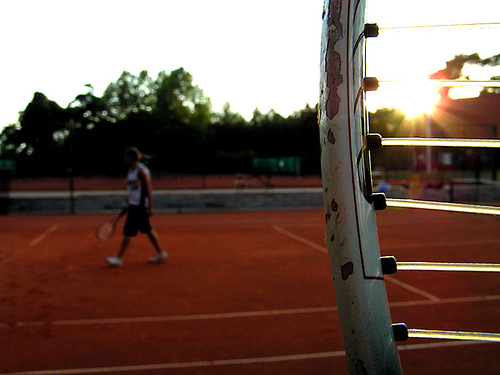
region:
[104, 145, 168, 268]
tennis player on court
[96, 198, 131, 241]
tennis racket in player's hand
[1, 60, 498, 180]
trees in back of court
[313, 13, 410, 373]
pole holding cables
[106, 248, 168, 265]
sneakers on player's feet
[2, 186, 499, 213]
wall around tennis court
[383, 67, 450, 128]
sun in sky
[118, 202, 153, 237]
black shorts on player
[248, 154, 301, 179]
green container in background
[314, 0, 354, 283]
rust on pole near tennis court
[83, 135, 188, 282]
a tennis player on tennis court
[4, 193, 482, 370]
a red tennis court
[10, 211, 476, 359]
white lines on tennis court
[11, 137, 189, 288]
tennis player walks to the left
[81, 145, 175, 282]
tennis player holds a racket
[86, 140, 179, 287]
tennis player holds racket in right hand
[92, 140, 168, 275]
tennis player wears a top tank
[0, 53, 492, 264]
trees behind tennis court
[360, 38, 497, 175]
sun rays behind trees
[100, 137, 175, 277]
man wears black pants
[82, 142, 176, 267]
a person playing tennis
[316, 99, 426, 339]
a silver metal pole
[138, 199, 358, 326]
a red tennis court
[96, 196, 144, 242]
a tennis racket in a hand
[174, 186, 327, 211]
a concerte wall by court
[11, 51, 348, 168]
green leaft trees in back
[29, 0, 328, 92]
clear sky above trees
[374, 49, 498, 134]
sun shinning though trees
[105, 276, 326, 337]
white lines on tennis court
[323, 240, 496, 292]
strings hooked to metal pole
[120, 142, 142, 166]
The head of the player.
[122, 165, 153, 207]
The white tank top the player is wearing.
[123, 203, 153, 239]
The black shorts the player is wearing.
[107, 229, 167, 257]
The legs of the player.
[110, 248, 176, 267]
The white sneakers the player is wearing.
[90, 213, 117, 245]
The racket on the tennis racket.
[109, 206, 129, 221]
The handle of the tennis racket.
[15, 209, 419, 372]
The white boundary lines on the court.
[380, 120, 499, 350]
The four plastic posts attached to the metal pole.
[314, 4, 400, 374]
The metal pole the plastic spokes are attached to.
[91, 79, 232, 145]
Green trees in the background.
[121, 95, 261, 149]
Green trees in the background.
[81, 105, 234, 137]
Green trees in the background.